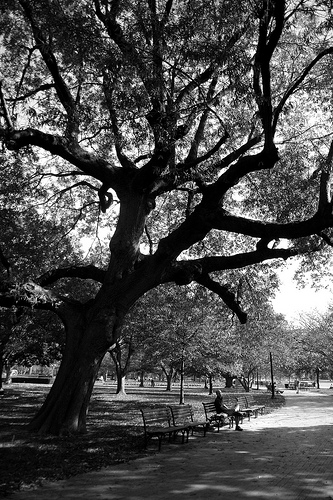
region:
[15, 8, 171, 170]
tree branches with scattered leaves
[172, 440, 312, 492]
shadow being cast on the sidewalk from the tree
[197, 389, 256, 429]
A man sitting on a bench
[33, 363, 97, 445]
A large tree trunk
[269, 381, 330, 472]
a park pathway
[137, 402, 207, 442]
a pair of park benches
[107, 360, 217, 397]
a group of trees in the park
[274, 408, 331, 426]
sun hitting the sidewalk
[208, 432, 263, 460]
leaves and debris on the ground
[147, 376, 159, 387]
a person walking in the distance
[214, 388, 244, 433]
The person sitting on the bench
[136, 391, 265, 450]
The benches under the tree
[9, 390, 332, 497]
The trail in front of the tree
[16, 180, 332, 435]
The large tree behind the benches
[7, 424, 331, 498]
The shadow of the large tree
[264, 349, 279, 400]
The street light next to the trail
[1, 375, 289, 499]
The grass lawn behind the benches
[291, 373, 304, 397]
The person on the trail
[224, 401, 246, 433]
The legs of the person on the bench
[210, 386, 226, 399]
The head of the person on the bench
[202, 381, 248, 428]
A person sitting on a bench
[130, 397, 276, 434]
A row of benches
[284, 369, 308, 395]
A person walking on the brick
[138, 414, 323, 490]
The pathway is made of brick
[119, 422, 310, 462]
There are leaves on the path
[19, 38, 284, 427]
Large tree with many branches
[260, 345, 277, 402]
Black light pole next to the path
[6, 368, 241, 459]
The trees are on the grass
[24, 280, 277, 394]
There are many trees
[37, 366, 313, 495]
The tree is shading the path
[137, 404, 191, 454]
metal and wooden park bench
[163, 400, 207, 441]
metal and wooden park bench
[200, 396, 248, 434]
metal and wooden park bench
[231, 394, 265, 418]
metal and wooden park bench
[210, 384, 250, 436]
man in dark clothing sitting on park bench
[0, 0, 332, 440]
large leaning tree with many twisted branches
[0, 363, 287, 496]
large green grassy field in park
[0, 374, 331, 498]
curved brick sidewalk going through park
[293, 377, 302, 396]
person standing in the middle of sidewalk in park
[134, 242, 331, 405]
trees lining sidewalk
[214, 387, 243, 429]
a man on a park bench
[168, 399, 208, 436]
an empty park bench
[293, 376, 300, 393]
a person standing on a walkway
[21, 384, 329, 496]
a brick paved walkway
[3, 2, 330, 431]
a large tree hanging over benches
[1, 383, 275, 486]
a field of grass under the trees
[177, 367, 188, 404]
a slender vertical tree trunk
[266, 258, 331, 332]
sky peeking through the trees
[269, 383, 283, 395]
a person on a bench in the distance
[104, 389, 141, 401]
light shining around the base of a tree